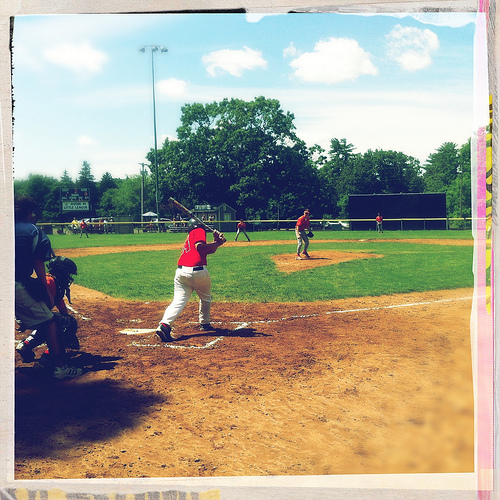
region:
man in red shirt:
[126, 173, 340, 485]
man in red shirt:
[112, 146, 273, 362]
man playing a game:
[122, 203, 244, 331]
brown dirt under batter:
[248, 333, 345, 409]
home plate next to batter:
[106, 308, 162, 360]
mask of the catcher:
[46, 243, 102, 298]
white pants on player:
[146, 257, 225, 320]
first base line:
[308, 284, 444, 336]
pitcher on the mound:
[274, 199, 339, 261]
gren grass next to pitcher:
[328, 260, 377, 298]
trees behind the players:
[197, 88, 305, 173]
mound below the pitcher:
[291, 236, 363, 283]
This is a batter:
[141, 186, 271, 366]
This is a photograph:
[6, 5, 491, 497]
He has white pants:
[146, 256, 256, 346]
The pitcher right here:
[275, 200, 333, 268]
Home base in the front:
[112, 307, 193, 359]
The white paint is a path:
[255, 273, 462, 353]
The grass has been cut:
[51, 187, 496, 395]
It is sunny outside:
[49, 26, 499, 274]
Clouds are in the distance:
[23, 17, 415, 169]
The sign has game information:
[49, 177, 110, 222]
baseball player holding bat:
[165, 190, 225, 312]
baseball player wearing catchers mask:
[52, 242, 86, 299]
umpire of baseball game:
[19, 188, 52, 323]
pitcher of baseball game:
[287, 195, 330, 285]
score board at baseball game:
[54, 178, 101, 211]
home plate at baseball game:
[123, 312, 157, 354]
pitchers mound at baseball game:
[272, 240, 366, 277]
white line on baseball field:
[276, 290, 443, 337]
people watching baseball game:
[95, 216, 137, 243]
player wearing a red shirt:
[155, 205, 250, 362]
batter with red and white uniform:
[153, 194, 227, 340]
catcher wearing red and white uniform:
[17, 255, 84, 362]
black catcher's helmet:
[45, 250, 80, 303]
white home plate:
[117, 325, 159, 338]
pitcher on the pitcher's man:
[292, 207, 314, 259]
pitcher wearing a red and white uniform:
[291, 207, 316, 258]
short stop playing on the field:
[230, 212, 251, 244]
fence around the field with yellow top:
[25, 214, 475, 236]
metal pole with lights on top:
[133, 40, 171, 231]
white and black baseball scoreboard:
[57, 183, 94, 218]